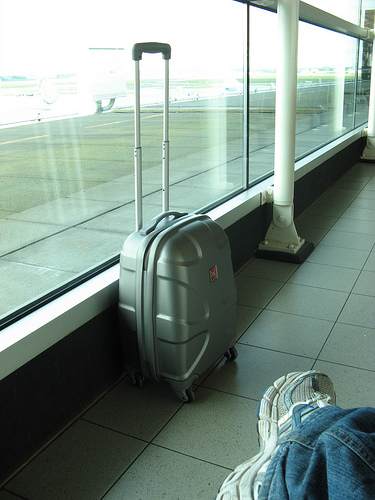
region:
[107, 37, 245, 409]
A silver travelling suit case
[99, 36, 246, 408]
A silver travelling suit case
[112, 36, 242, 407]
A silver travelling suit case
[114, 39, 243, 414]
A silver travelling suit case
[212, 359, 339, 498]
Grey and blue tennis shoe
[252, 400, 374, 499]
Blue jeans partially covering shoes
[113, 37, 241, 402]
Aluminum luggage with rollers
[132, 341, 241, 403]
Three wheels attached to luggage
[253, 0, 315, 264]
White metal building support pole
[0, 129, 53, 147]
Yellow lane stripe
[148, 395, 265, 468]
Grey tiled floor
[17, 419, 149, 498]
white tile on floor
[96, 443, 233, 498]
white tile on floor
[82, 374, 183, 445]
white tile on floor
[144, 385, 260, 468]
white tile on floor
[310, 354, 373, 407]
white tile on floor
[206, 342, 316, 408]
white tile on floor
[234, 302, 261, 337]
white tile on floor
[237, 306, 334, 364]
white tile on floor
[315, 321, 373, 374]
white tile on floor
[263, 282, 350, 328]
white tile on floor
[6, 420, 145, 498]
white colored floor tile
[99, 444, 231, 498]
white colored floor tile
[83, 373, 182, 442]
white colored floor tile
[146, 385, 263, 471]
white colored floor tile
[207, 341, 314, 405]
white colored floor tile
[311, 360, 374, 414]
white colored floor tile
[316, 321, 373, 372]
white colored floor tile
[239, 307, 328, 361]
white colored floor tile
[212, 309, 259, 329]
white colored floor tile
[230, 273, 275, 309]
white colored floor tile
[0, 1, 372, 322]
wall of clear windows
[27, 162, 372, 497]
square tiles on floor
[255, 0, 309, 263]
pole bolted into base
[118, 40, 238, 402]
luggage with raised handle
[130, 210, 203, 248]
handle on top of luggage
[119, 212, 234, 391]
luggage with hard surface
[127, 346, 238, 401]
wheels on bottom of luggage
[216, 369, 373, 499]
human leg and foot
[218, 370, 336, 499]
side of white sneaker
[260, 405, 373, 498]
bottom of blue jean leg